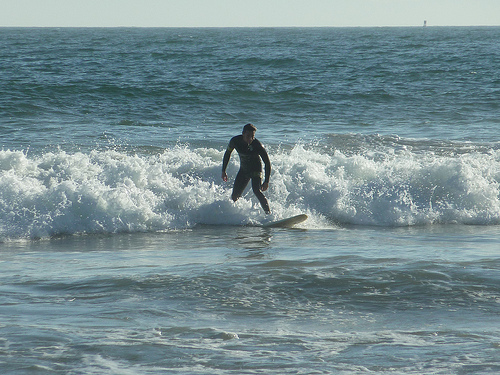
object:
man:
[218, 122, 275, 216]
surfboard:
[257, 212, 306, 231]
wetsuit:
[224, 135, 270, 213]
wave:
[307, 141, 498, 229]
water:
[0, 29, 217, 236]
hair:
[243, 123, 258, 135]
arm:
[258, 144, 272, 192]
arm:
[221, 140, 235, 182]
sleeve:
[260, 144, 271, 178]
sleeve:
[221, 139, 234, 167]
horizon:
[1, 22, 499, 30]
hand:
[260, 182, 269, 191]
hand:
[221, 171, 229, 183]